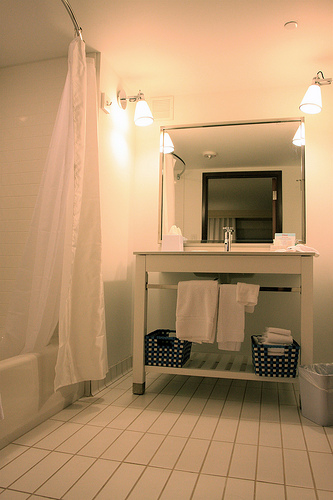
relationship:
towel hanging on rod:
[174, 279, 219, 348] [145, 281, 304, 295]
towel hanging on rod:
[215, 285, 246, 350] [145, 281, 304, 295]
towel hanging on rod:
[235, 281, 260, 315] [145, 281, 304, 295]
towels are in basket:
[260, 325, 293, 359] [250, 334, 302, 380]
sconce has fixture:
[133, 100, 154, 130] [116, 88, 146, 112]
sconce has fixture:
[298, 83, 324, 117] [312, 71, 332, 88]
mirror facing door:
[157, 118, 307, 248] [200, 169, 284, 245]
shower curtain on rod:
[25, 38, 109, 392] [58, 2, 85, 41]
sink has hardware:
[131, 247, 319, 262] [221, 224, 236, 252]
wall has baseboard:
[92, 53, 151, 395] [84, 354, 133, 396]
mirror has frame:
[157, 118, 307, 248] [157, 116, 307, 246]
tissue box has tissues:
[160, 234, 185, 253] [166, 226, 183, 236]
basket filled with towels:
[250, 334, 302, 380] [260, 325, 293, 359]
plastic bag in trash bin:
[294, 362, 332, 392] [297, 362, 331, 426]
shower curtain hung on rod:
[25, 38, 109, 392] [58, 2, 85, 41]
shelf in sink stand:
[145, 350, 302, 385] [131, 248, 321, 396]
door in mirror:
[200, 169, 284, 245] [157, 118, 307, 248]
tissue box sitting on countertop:
[160, 234, 185, 253] [131, 246, 320, 260]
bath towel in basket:
[261, 333, 295, 345] [250, 334, 302, 380]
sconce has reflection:
[133, 100, 154, 130] [160, 129, 174, 154]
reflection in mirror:
[160, 129, 174, 154] [157, 118, 307, 248]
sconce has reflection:
[298, 83, 324, 117] [292, 123, 307, 149]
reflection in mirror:
[292, 123, 307, 149] [157, 118, 307, 248]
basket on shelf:
[143, 328, 191, 369] [145, 350, 302, 385]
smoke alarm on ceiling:
[283, 20, 297, 34] [2, 2, 332, 87]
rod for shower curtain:
[58, 2, 85, 41] [25, 38, 109, 392]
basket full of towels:
[250, 334, 302, 380] [260, 325, 293, 359]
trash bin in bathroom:
[297, 362, 331, 426] [2, 0, 330, 499]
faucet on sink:
[221, 224, 236, 252] [131, 247, 319, 262]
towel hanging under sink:
[174, 279, 219, 348] [131, 247, 319, 262]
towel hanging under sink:
[215, 285, 246, 350] [131, 247, 319, 262]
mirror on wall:
[157, 118, 307, 248] [131, 83, 332, 367]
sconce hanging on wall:
[133, 100, 154, 130] [92, 53, 151, 395]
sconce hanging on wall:
[298, 83, 324, 117] [131, 83, 332, 367]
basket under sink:
[250, 334, 302, 380] [131, 247, 319, 262]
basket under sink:
[143, 328, 191, 369] [131, 247, 319, 262]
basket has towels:
[250, 334, 302, 380] [260, 325, 293, 359]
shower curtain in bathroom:
[25, 38, 109, 392] [2, 0, 330, 499]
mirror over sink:
[157, 118, 307, 248] [131, 247, 319, 262]